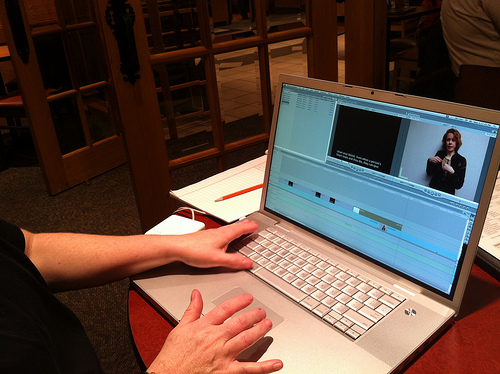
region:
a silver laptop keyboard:
[224, 224, 409, 341]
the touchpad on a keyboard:
[212, 284, 283, 334]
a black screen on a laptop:
[327, 99, 409, 177]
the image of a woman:
[399, 116, 490, 203]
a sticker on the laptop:
[401, 305, 418, 317]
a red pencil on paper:
[211, 182, 261, 202]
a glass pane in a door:
[48, 99, 88, 154]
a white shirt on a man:
[436, 0, 498, 75]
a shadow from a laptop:
[460, 266, 498, 316]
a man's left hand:
[174, 217, 259, 271]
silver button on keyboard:
[390, 292, 404, 304]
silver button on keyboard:
[378, 293, 398, 308]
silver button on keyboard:
[374, 302, 388, 314]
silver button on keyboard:
[358, 304, 383, 322]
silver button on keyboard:
[343, 305, 372, 327]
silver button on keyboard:
[339, 315, 351, 325]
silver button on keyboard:
[345, 328, 358, 340]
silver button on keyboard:
[333, 318, 347, 331]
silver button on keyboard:
[319, 310, 338, 327]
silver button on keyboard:
[298, 293, 318, 311]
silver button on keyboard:
[379, 285, 394, 294]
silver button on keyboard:
[356, 273, 371, 283]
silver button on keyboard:
[311, 302, 332, 316]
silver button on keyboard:
[332, 299, 349, 319]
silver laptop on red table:
[120, 64, 497, 365]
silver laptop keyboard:
[243, 224, 409, 344]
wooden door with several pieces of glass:
[98, 7, 340, 206]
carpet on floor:
[77, 192, 123, 232]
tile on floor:
[217, 65, 252, 97]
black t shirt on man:
[0, 174, 85, 372]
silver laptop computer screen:
[260, 78, 498, 302]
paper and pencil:
[165, 147, 274, 222]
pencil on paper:
[211, 177, 262, 202]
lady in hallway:
[422, 127, 477, 197]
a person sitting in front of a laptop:
[0, 215, 283, 370]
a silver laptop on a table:
[133, 75, 499, 366]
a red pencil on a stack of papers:
[212, 180, 262, 198]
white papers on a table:
[167, 153, 266, 220]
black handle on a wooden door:
[104, 0, 143, 85]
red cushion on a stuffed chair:
[1, 84, 67, 116]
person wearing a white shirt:
[439, 3, 499, 74]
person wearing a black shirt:
[1, 218, 102, 372]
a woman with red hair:
[441, 126, 463, 156]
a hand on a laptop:
[149, 287, 279, 369]